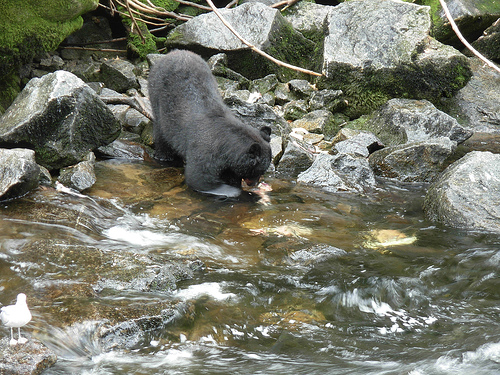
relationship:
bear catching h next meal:
[142, 48, 280, 188] [227, 168, 276, 212]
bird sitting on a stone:
[9, 293, 35, 345] [4, 340, 49, 374]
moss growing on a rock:
[337, 60, 468, 116] [320, 7, 460, 96]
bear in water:
[142, 48, 280, 188] [2, 141, 499, 372]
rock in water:
[10, 70, 127, 163] [2, 141, 499, 372]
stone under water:
[35, 182, 94, 237] [2, 141, 499, 372]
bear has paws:
[142, 48, 280, 188] [216, 187, 266, 208]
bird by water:
[9, 293, 35, 345] [2, 141, 499, 372]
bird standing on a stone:
[9, 293, 35, 345] [4, 340, 49, 374]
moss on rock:
[337, 60, 468, 116] [320, 7, 460, 96]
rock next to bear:
[10, 70, 127, 163] [142, 48, 280, 188]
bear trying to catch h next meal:
[142, 48, 280, 188] [227, 168, 276, 212]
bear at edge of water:
[142, 48, 280, 188] [2, 141, 499, 372]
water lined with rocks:
[2, 141, 499, 372] [4, 1, 499, 206]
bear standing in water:
[142, 48, 280, 188] [2, 141, 499, 372]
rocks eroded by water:
[4, 1, 499, 206] [2, 141, 499, 372]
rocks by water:
[4, 1, 499, 206] [2, 141, 499, 372]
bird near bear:
[9, 293, 35, 345] [142, 48, 280, 188]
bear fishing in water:
[142, 48, 280, 188] [2, 141, 499, 372]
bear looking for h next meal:
[142, 48, 280, 188] [227, 168, 276, 212]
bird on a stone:
[9, 293, 35, 345] [4, 340, 49, 374]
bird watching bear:
[9, 293, 35, 345] [142, 48, 280, 188]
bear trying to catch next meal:
[142, 48, 280, 188] [227, 168, 276, 212]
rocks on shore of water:
[4, 1, 499, 206] [2, 141, 499, 372]